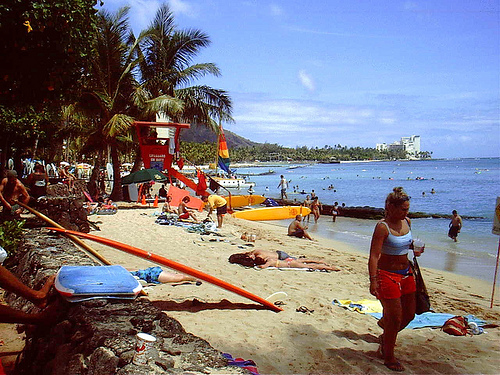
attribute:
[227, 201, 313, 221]
sufboard — yellow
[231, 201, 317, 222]
surfboard — yellow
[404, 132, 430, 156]
building — white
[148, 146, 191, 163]
sailboat — rainbow colored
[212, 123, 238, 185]
flag — rainbow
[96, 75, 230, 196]
lifeguard — red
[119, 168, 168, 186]
umbrella — green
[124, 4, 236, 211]
palm tree — tall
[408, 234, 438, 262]
cup — plastic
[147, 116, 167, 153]
guard — life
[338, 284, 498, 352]
towel — light, blue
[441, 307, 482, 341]
bag — red, white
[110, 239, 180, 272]
surfboard — orange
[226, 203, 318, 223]
surfboard — long, yellow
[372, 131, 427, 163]
building — tall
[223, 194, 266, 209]
surfboard — yellow, long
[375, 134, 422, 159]
building — tall, green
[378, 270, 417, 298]
shorts — orange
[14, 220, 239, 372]
wall — long, dark, rock